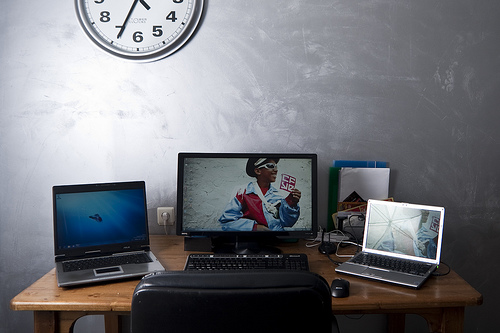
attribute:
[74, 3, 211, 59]
clock — silver, big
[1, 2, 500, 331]
wall — white, silver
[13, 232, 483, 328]
desk — wooden, brown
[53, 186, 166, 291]
laptop — black, silver, small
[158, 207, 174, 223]
outlet — white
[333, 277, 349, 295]
mouse — black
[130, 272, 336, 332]
chair — leather, black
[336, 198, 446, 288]
laptop — silver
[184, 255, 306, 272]
keyboard — black